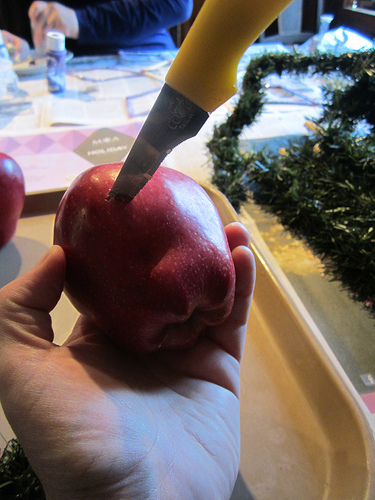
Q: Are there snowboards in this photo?
A: No, there are no snowboards.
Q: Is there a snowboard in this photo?
A: No, there are no snowboards.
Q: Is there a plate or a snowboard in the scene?
A: No, there are no snowboards or plates.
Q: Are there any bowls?
A: No, there are no bowls.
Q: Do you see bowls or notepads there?
A: No, there are no bowls or notepads.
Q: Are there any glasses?
A: No, there are no glasses.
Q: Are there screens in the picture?
A: No, there are no screens.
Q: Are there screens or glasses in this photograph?
A: No, there are no screens or glasses.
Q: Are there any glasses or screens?
A: No, there are no screens or glasses.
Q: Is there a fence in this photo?
A: No, there are no fences.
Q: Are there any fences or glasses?
A: No, there are no fences or glasses.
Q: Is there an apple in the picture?
A: Yes, there is an apple.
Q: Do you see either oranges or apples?
A: Yes, there is an apple.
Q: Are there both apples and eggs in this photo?
A: No, there is an apple but no eggs.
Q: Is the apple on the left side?
A: Yes, the apple is on the left of the image.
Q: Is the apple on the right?
A: No, the apple is on the left of the image.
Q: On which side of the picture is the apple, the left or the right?
A: The apple is on the left of the image.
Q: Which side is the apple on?
A: The apple is on the left of the image.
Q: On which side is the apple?
A: The apple is on the left of the image.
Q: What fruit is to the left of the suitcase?
A: The fruit is an apple.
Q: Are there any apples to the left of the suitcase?
A: Yes, there is an apple to the left of the suitcase.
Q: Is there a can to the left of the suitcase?
A: No, there is an apple to the left of the suitcase.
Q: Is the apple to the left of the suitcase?
A: Yes, the apple is to the left of the suitcase.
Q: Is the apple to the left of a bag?
A: No, the apple is to the left of the suitcase.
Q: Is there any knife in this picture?
A: Yes, there is a knife.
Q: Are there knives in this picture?
A: Yes, there is a knife.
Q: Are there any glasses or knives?
A: Yes, there is a knife.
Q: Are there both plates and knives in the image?
A: No, there is a knife but no plates.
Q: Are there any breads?
A: No, there are no breads.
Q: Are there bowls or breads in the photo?
A: No, there are no breads or bowls.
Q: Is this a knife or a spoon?
A: This is a knife.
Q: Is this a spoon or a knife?
A: This is a knife.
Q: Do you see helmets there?
A: No, there are no helmets.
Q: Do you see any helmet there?
A: No, there are no helmets.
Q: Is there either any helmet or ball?
A: No, there are no helmets or balls.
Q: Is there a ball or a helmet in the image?
A: No, there are no helmets or balls.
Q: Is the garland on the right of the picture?
A: Yes, the garland is on the right of the image.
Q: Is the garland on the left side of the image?
A: No, the garland is on the right of the image.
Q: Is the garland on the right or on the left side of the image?
A: The garland is on the right of the image.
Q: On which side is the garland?
A: The garland is on the right of the image.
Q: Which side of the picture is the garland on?
A: The garland is on the right of the image.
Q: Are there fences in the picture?
A: No, there are no fences.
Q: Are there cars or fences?
A: No, there are no fences or cars.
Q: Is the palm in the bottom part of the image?
A: Yes, the palm is in the bottom of the image.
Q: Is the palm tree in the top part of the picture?
A: No, the palm tree is in the bottom of the image.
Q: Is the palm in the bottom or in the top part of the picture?
A: The palm is in the bottom of the image.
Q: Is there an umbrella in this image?
A: No, there are no umbrellas.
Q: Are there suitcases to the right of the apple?
A: Yes, there is a suitcase to the right of the apple.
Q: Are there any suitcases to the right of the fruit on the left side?
A: Yes, there is a suitcase to the right of the apple.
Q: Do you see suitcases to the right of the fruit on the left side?
A: Yes, there is a suitcase to the right of the apple.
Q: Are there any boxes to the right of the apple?
A: No, there is a suitcase to the right of the apple.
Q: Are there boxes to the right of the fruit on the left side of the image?
A: No, there is a suitcase to the right of the apple.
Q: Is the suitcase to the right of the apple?
A: Yes, the suitcase is to the right of the apple.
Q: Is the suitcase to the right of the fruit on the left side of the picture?
A: Yes, the suitcase is to the right of the apple.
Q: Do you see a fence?
A: No, there are no fences.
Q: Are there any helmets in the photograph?
A: No, there are no helmets.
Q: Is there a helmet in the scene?
A: No, there are no helmets.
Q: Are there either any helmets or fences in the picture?
A: No, there are no helmets or fences.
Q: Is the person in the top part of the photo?
A: Yes, the person is in the top of the image.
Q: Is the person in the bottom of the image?
A: No, the person is in the top of the image.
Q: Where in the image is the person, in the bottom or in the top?
A: The person is in the top of the image.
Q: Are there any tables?
A: Yes, there is a table.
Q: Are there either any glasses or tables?
A: Yes, there is a table.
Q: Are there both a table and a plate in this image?
A: No, there is a table but no plates.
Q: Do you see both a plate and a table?
A: No, there is a table but no plates.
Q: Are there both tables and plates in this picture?
A: No, there is a table but no plates.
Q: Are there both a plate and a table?
A: No, there is a table but no plates.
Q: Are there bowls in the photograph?
A: No, there are no bowls.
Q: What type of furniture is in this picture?
A: The furniture is a table.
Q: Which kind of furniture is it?
A: The piece of furniture is a table.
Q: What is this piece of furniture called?
A: This is a table.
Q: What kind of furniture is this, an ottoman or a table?
A: This is a table.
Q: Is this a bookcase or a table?
A: This is a table.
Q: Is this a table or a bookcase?
A: This is a table.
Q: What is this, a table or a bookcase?
A: This is a table.